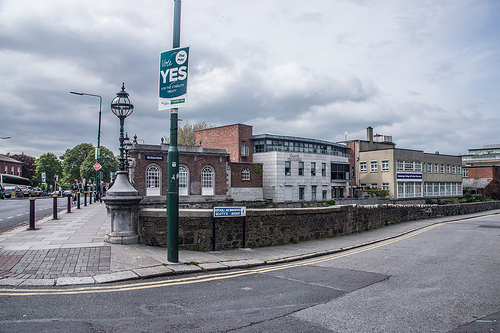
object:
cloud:
[0, 0, 497, 162]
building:
[335, 139, 396, 197]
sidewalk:
[0, 208, 500, 289]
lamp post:
[93, 97, 102, 193]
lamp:
[110, 81, 135, 119]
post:
[165, 0, 183, 264]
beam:
[435, 7, 479, 82]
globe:
[110, 95, 134, 119]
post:
[110, 81, 135, 170]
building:
[252, 150, 356, 207]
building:
[461, 163, 499, 199]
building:
[125, 134, 264, 209]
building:
[463, 159, 500, 166]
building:
[0, 153, 24, 182]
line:
[0, 212, 500, 296]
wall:
[137, 203, 500, 250]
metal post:
[166, 108, 181, 263]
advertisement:
[157, 46, 191, 111]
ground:
[0, 193, 500, 333]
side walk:
[0, 192, 111, 280]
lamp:
[69, 91, 99, 97]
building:
[357, 147, 464, 200]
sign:
[157, 46, 191, 112]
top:
[249, 133, 350, 154]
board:
[213, 206, 247, 218]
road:
[0, 194, 500, 333]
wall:
[226, 162, 265, 201]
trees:
[78, 145, 120, 184]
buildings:
[194, 122, 253, 162]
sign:
[395, 171, 422, 182]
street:
[0, 212, 500, 331]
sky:
[0, 0, 500, 161]